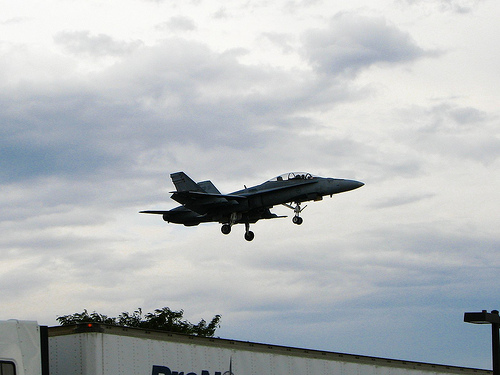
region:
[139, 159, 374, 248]
jet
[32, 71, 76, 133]
white clouds in blue sky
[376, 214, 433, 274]
white clouds in blue sky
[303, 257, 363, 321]
white clouds in blue sky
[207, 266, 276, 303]
white clouds in blue sky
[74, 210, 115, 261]
white clouds in blue sky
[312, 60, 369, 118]
white clouds in blue sky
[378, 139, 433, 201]
white clouds in blue sky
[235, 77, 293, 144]
white clouds in blue sky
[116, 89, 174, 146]
white clouds in blue sky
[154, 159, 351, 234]
f18 preparing to land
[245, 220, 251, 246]
landing gear of f18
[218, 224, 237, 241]
landing gear of f18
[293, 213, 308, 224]
landing gear of f18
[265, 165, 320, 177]
glass cockpit of plane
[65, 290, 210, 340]
tree growing behind truck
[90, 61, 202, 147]
white clouds in sky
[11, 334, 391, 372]
white semi truck under plane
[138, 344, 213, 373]
black writing on truck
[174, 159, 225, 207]
tail of f18 fighter jet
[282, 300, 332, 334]
white clouds in blue sky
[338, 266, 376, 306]
white clouds in blue sky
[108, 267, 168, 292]
white clouds in blue sky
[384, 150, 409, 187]
white clouds in blue sky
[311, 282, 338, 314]
white clouds in blue sky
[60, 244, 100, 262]
white clouds in blue sky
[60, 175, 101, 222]
white clouds in blue sky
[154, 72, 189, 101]
white clouds in blue sky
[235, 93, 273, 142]
white clouds in blue sky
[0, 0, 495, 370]
Cloud filled sky with a jet flying in it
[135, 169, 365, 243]
Jet with landing gear extended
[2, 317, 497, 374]
Side of a white truck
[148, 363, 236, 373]
Top edges of lettering on white metal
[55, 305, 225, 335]
Top of trees visible over the edge of a truck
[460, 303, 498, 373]
Light on a light pole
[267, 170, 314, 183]
Clear hatch on a plane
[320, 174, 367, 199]
Pointed nose of a jet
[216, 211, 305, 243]
Three sets of wheels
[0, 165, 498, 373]
A jet flying low over a truck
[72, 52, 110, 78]
white clouds in blue sky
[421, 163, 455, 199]
white clouds in blue sky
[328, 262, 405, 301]
white clouds in blue sky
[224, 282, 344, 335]
white clouds in blue sky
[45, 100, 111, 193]
white clouds in blue sky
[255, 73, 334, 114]
white clouds in blue sky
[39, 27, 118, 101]
white clouds in blue sky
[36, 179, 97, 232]
white clouds in blue sky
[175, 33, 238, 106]
white clouds in blue sky